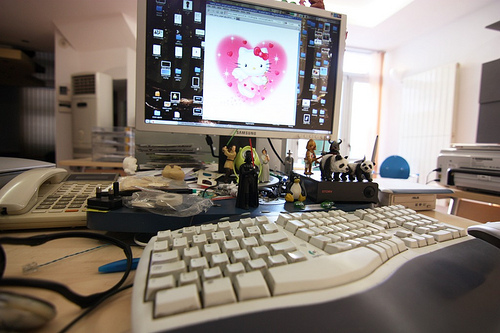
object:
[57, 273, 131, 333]
rope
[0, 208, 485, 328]
table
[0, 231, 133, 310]
wire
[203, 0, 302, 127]
window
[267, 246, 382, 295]
button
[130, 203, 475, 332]
butt ons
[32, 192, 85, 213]
buttons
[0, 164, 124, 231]
phone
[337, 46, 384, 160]
window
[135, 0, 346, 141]
computer screen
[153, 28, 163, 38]
icons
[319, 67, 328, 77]
icons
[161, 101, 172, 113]
icons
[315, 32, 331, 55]
icons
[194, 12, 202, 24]
icons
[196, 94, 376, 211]
blue surface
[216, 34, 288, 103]
heart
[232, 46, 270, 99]
hello kitty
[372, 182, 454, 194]
table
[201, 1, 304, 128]
image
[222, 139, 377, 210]
figurines